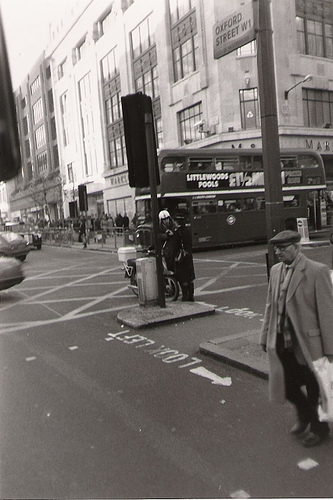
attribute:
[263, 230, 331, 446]
man — old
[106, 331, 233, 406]
street print — white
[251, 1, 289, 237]
pole — black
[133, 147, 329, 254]
bus — double decker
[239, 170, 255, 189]
1/2 — white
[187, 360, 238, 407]
arrow — white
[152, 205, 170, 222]
helmet — white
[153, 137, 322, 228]
bus — double decker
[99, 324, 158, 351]
print — white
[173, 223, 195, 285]
coat — long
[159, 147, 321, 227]
bus — Large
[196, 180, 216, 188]
text — white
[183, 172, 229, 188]
print — white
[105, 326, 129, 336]
letter — white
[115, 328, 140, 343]
letter — white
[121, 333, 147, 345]
letter — white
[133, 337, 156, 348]
letter — white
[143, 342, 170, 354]
letter — white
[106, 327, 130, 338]
mark — white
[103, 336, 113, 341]
mark — white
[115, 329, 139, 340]
mark — white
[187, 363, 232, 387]
mark — white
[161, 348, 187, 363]
mark — white